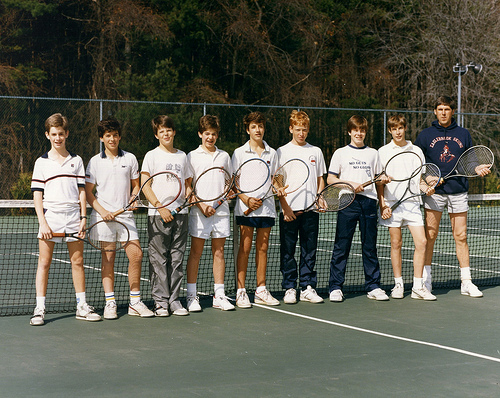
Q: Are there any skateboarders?
A: No, there are no skateboarders.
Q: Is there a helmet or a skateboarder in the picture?
A: No, there are no skateboarders or helmets.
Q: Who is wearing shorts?
A: The boy is wearing shorts.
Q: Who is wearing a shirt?
A: The boy is wearing a shirt.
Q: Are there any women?
A: No, there are no women.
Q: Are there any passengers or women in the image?
A: No, there are no women or passengers.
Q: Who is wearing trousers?
A: The boy is wearing trousers.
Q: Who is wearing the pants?
A: The boy is wearing trousers.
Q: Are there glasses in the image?
A: No, there are no glasses.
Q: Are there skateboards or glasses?
A: No, there are no glasses or skateboards.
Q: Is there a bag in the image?
A: No, there are no bags.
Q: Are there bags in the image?
A: No, there are no bags.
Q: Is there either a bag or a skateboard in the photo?
A: No, there are no bags or skateboards.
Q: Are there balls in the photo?
A: No, there are no balls.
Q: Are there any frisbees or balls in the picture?
A: No, there are no balls or frisbees.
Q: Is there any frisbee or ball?
A: No, there are no balls or frisbees.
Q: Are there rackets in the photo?
A: Yes, there is a racket.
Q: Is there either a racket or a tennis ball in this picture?
A: Yes, there is a racket.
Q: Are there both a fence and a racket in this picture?
A: Yes, there are both a racket and a fence.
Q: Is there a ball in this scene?
A: No, there are no balls.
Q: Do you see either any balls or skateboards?
A: No, there are no balls or skateboards.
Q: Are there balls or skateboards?
A: No, there are no balls or skateboards.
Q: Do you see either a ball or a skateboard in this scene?
A: No, there are no balls or skateboards.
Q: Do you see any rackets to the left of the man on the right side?
A: Yes, there is a racket to the left of the man.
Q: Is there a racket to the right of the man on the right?
A: No, the racket is to the left of the man.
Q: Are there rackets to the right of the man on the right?
A: No, the racket is to the left of the man.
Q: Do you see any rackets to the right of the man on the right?
A: No, the racket is to the left of the man.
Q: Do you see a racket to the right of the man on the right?
A: No, the racket is to the left of the man.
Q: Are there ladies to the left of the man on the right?
A: No, there is a racket to the left of the man.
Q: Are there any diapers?
A: No, there are no diapers.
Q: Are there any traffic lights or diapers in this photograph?
A: No, there are no diapers or traffic lights.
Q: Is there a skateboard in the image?
A: No, there are no skateboards.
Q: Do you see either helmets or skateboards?
A: No, there are no skateboards or helmets.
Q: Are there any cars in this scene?
A: No, there are no cars.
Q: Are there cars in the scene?
A: No, there are no cars.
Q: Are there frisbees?
A: No, there are no frisbees.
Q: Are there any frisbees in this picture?
A: No, there are no frisbees.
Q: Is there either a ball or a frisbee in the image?
A: No, there are no frisbees or balls.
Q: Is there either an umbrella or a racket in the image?
A: Yes, there is a racket.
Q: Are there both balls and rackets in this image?
A: No, there is a racket but no balls.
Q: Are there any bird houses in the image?
A: No, there are no bird houses.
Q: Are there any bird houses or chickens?
A: No, there are no bird houses or chickens.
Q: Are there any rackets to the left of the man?
A: Yes, there is a racket to the left of the man.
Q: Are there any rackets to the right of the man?
A: No, the racket is to the left of the man.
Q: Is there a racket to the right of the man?
A: No, the racket is to the left of the man.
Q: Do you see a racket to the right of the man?
A: No, the racket is to the left of the man.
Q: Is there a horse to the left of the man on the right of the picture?
A: No, there is a racket to the left of the man.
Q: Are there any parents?
A: No, there are no parents.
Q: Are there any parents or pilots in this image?
A: No, there are no parents or pilots.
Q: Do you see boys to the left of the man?
A: Yes, there is a boy to the left of the man.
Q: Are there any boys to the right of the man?
A: No, the boy is to the left of the man.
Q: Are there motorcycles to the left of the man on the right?
A: No, there is a boy to the left of the man.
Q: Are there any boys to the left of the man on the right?
A: Yes, there is a boy to the left of the man.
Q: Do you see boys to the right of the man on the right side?
A: No, the boy is to the left of the man.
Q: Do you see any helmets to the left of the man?
A: No, there is a boy to the left of the man.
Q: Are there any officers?
A: No, there are no officers.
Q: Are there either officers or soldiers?
A: No, there are no officers or soldiers.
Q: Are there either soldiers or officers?
A: No, there are no officers or soldiers.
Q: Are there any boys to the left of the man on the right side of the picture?
A: Yes, there is a boy to the left of the man.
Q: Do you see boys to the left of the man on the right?
A: Yes, there is a boy to the left of the man.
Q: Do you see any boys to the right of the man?
A: No, the boy is to the left of the man.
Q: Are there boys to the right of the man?
A: No, the boy is to the left of the man.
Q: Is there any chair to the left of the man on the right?
A: No, there is a boy to the left of the man.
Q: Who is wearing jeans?
A: The boy is wearing jeans.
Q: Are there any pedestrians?
A: No, there are no pedestrians.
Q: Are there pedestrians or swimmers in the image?
A: No, there are no pedestrians or swimmers.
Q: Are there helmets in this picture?
A: No, there are no helmets.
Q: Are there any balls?
A: No, there are no balls.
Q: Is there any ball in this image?
A: No, there are no balls.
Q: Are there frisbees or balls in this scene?
A: No, there are no balls or frisbees.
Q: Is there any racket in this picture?
A: Yes, there is a racket.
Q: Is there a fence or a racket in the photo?
A: Yes, there is a racket.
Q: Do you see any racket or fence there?
A: Yes, there is a racket.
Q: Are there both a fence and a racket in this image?
A: Yes, there are both a racket and a fence.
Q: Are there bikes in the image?
A: No, there are no bikes.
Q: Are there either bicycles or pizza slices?
A: No, there are no bicycles or pizza slices.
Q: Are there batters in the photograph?
A: No, there are no batters.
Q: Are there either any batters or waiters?
A: No, there are no batters or waiters.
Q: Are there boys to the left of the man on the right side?
A: Yes, there is a boy to the left of the man.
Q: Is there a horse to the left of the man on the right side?
A: No, there is a boy to the left of the man.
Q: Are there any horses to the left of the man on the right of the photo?
A: No, there is a boy to the left of the man.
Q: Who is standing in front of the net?
A: The boy is standing in front of the net.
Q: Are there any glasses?
A: No, there are no glasses.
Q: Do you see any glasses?
A: No, there are no glasses.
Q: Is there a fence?
A: Yes, there is a fence.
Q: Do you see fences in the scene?
A: Yes, there is a fence.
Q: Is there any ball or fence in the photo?
A: Yes, there is a fence.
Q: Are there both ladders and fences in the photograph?
A: No, there is a fence but no ladders.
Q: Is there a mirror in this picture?
A: No, there are no mirrors.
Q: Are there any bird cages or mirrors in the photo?
A: No, there are no mirrors or bird cages.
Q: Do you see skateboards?
A: No, there are no skateboards.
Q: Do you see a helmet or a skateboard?
A: No, there are no skateboards or helmets.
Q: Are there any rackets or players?
A: Yes, there is a racket.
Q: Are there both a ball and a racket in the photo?
A: No, there is a racket but no balls.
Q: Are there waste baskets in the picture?
A: No, there are no waste baskets.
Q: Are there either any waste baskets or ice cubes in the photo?
A: No, there are no waste baskets or ice cubes.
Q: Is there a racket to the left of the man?
A: Yes, there is a racket to the left of the man.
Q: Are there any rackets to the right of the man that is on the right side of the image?
A: No, the racket is to the left of the man.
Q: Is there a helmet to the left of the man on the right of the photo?
A: No, there is a racket to the left of the man.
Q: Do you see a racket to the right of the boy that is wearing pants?
A: Yes, there is a racket to the right of the boy.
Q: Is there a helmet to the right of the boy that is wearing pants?
A: No, there is a racket to the right of the boy.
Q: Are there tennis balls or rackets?
A: Yes, there is a racket.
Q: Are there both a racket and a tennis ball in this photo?
A: No, there is a racket but no tennis balls.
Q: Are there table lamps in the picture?
A: No, there are no table lamps.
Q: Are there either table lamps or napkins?
A: No, there are no table lamps or napkins.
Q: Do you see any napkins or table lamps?
A: No, there are no table lamps or napkins.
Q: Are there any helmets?
A: No, there are no helmets.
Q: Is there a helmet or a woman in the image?
A: No, there are no helmets or women.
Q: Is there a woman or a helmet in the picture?
A: No, there are no helmets or women.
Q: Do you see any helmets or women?
A: No, there are no helmets or women.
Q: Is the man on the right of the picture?
A: Yes, the man is on the right of the image.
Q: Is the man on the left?
A: No, the man is on the right of the image.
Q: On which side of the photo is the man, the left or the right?
A: The man is on the right of the image.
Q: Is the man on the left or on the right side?
A: The man is on the right of the image.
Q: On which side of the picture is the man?
A: The man is on the right of the image.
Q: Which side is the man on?
A: The man is on the right of the image.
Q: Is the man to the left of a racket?
A: No, the man is to the right of a racket.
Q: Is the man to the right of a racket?
A: Yes, the man is to the right of a racket.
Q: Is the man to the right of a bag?
A: No, the man is to the right of a racket.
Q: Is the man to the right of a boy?
A: Yes, the man is to the right of a boy.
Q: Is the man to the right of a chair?
A: No, the man is to the right of a boy.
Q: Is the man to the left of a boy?
A: No, the man is to the right of a boy.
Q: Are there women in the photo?
A: No, there are no women.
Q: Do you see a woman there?
A: No, there are no women.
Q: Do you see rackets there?
A: Yes, there is a racket.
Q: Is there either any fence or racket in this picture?
A: Yes, there is a racket.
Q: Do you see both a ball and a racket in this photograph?
A: No, there is a racket but no balls.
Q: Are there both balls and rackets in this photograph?
A: No, there is a racket but no balls.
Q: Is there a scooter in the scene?
A: No, there are no scooters.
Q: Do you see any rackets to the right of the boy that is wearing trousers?
A: Yes, there is a racket to the right of the boy.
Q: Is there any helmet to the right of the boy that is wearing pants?
A: No, there is a racket to the right of the boy.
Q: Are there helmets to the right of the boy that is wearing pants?
A: No, there is a racket to the right of the boy.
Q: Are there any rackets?
A: Yes, there is a racket.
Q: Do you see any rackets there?
A: Yes, there is a racket.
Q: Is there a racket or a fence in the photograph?
A: Yes, there is a racket.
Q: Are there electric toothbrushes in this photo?
A: No, there are no electric toothbrushes.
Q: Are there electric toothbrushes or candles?
A: No, there are no electric toothbrushes or candles.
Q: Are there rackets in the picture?
A: Yes, there is a racket.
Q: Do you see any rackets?
A: Yes, there is a racket.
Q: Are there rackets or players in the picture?
A: Yes, there is a racket.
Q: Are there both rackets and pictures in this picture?
A: No, there is a racket but no pictures.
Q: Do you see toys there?
A: No, there are no toys.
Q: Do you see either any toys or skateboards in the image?
A: No, there are no toys or skateboards.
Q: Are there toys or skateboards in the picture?
A: No, there are no toys or skateboards.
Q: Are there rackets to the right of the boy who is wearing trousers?
A: Yes, there is a racket to the right of the boy.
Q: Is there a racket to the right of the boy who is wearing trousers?
A: Yes, there is a racket to the right of the boy.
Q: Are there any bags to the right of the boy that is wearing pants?
A: No, there is a racket to the right of the boy.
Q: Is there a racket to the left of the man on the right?
A: Yes, there is a racket to the left of the man.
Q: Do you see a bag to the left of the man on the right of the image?
A: No, there is a racket to the left of the man.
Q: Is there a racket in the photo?
A: Yes, there is a racket.